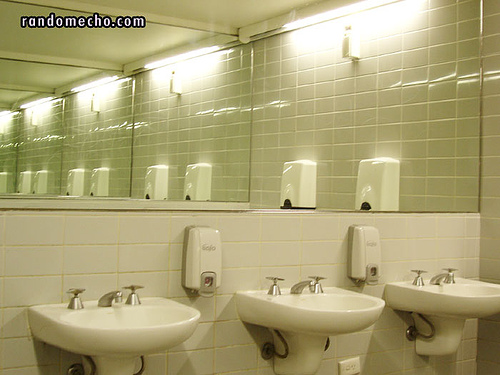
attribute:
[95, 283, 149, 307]
faucet — silver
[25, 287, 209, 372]
sink — white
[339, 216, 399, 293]
dispenser — white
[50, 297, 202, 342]
sink bowl — white, large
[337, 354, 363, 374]
outlet plate — white, small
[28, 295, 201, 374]
sink — white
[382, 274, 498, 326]
sink — white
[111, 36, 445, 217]
mirror — large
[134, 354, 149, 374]
tube — metal wiring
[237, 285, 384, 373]
sink — white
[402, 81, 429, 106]
tile — white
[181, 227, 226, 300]
dispenser — white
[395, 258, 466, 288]
faucet — silver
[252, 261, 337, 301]
faucet — silver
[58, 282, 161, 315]
faucet — silver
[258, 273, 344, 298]
faucet — silver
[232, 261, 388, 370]
sink — white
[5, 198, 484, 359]
wall — white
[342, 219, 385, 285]
dispenser — hanging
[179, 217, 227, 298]
dispenser — hanging